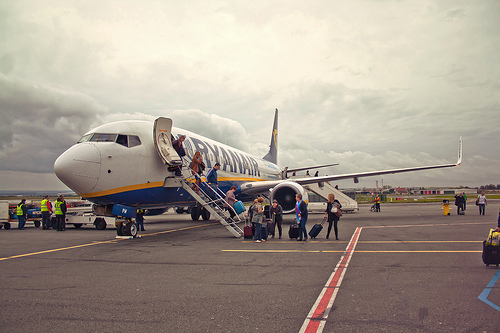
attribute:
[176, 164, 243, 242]
stairs — metal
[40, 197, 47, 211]
vest — bright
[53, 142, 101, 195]
nose — white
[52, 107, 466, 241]
plane — yellow, white, jet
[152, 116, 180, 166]
door — white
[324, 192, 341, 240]
person — standing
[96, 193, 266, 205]
belly — blue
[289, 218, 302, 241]
bag — dark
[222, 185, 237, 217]
person — passenger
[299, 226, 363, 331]
line — red, stripe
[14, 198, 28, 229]
worker — handler, standing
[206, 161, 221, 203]
person — passenger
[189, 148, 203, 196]
woman — passenger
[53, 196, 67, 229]
worker — standing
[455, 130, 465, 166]
tip — vertical